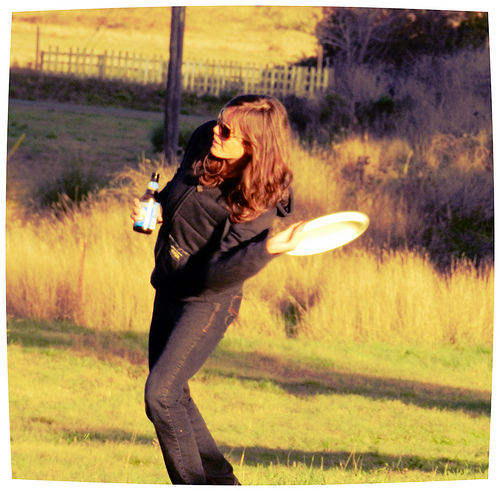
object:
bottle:
[133, 171, 161, 235]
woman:
[129, 93, 302, 486]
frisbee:
[285, 210, 370, 255]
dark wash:
[177, 328, 199, 343]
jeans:
[143, 282, 243, 489]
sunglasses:
[216, 118, 246, 140]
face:
[211, 112, 245, 159]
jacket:
[150, 120, 292, 294]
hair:
[189, 93, 295, 224]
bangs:
[218, 104, 240, 123]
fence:
[26, 33, 326, 97]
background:
[13, 6, 490, 275]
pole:
[162, 5, 186, 164]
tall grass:
[9, 51, 497, 351]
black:
[189, 201, 226, 262]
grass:
[7, 311, 498, 483]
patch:
[7, 98, 158, 193]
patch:
[183, 319, 486, 476]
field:
[28, 106, 470, 478]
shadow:
[217, 438, 485, 477]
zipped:
[153, 178, 206, 264]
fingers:
[130, 197, 140, 221]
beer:
[133, 172, 161, 235]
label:
[135, 202, 162, 230]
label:
[147, 181, 159, 190]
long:
[247, 124, 292, 216]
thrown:
[206, 192, 371, 292]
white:
[325, 232, 337, 244]